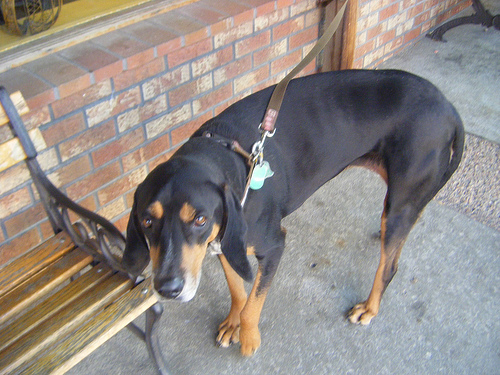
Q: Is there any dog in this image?
A: Yes, there is a dog.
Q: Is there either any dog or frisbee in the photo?
A: Yes, there is a dog.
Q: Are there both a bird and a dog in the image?
A: No, there is a dog but no birds.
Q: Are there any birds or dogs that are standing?
A: Yes, the dog is standing.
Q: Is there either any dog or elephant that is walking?
A: Yes, the dog is walking.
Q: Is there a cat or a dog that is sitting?
A: Yes, the dog is sitting.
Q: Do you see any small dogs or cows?
A: Yes, there is a small dog.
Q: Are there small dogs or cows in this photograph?
A: Yes, there is a small dog.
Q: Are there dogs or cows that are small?
A: Yes, the dog is small.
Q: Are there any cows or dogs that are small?
A: Yes, the dog is small.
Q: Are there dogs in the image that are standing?
A: Yes, there is a dog that is standing.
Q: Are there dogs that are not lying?
A: Yes, there is a dog that is standing.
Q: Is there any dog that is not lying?
A: Yes, there is a dog that is standing.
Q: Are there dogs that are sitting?
A: Yes, there is a dog that is sitting.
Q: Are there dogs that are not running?
A: Yes, there is a dog that is sitting.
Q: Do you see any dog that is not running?
A: Yes, there is a dog that is sitting .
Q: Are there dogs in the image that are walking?
A: Yes, there is a dog that is walking.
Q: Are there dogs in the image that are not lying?
A: Yes, there is a dog that is walking.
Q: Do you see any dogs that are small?
A: Yes, there is a small dog.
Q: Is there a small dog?
A: Yes, there is a small dog.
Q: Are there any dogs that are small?
A: Yes, there is a dog that is small.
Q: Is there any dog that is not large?
A: Yes, there is a small dog.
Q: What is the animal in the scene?
A: The animal is a dog.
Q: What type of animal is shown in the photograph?
A: The animal is a dog.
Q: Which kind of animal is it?
A: The animal is a dog.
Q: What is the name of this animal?
A: That is a dog.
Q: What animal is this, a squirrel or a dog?
A: That is a dog.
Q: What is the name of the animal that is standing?
A: The animal is a dog.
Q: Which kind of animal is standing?
A: The animal is a dog.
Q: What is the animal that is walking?
A: The animal is a dog.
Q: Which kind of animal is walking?
A: The animal is a dog.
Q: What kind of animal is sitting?
A: The animal is a dog.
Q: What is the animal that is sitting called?
A: The animal is a dog.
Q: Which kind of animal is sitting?
A: The animal is a dog.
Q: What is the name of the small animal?
A: The animal is a dog.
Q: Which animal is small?
A: The animal is a dog.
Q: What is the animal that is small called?
A: The animal is a dog.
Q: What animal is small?
A: The animal is a dog.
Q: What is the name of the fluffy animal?
A: The animal is a dog.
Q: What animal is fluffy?
A: The animal is a dog.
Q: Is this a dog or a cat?
A: This is a dog.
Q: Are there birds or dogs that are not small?
A: No, there is a dog but it is small.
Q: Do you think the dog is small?
A: Yes, the dog is small.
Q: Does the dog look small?
A: Yes, the dog is small.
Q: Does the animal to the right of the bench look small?
A: Yes, the dog is small.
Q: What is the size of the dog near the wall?
A: The dog is small.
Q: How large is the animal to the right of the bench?
A: The dog is small.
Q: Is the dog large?
A: No, the dog is small.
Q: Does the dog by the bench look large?
A: No, the dog is small.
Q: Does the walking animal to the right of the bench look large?
A: No, the dog is small.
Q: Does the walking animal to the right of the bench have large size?
A: No, the dog is small.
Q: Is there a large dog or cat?
A: No, there is a dog but it is small.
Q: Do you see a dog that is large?
A: No, there is a dog but it is small.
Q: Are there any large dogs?
A: No, there is a dog but it is small.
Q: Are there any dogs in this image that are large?
A: No, there is a dog but it is small.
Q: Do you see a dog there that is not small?
A: No, there is a dog but it is small.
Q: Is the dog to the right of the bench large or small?
A: The dog is small.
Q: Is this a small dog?
A: Yes, this is a small dog.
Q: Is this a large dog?
A: No, this is a small dog.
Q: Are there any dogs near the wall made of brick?
A: Yes, there is a dog near the wall.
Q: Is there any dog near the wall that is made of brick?
A: Yes, there is a dog near the wall.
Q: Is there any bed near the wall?
A: No, there is a dog near the wall.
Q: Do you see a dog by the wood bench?
A: Yes, there is a dog by the bench.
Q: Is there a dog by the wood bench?
A: Yes, there is a dog by the bench.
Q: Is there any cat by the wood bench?
A: No, there is a dog by the bench.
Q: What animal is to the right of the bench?
A: The animal is a dog.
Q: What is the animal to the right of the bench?
A: The animal is a dog.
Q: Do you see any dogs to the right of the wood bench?
A: Yes, there is a dog to the right of the bench.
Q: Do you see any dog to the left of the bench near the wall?
A: No, the dog is to the right of the bench.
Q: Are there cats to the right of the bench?
A: No, there is a dog to the right of the bench.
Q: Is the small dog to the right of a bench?
A: Yes, the dog is to the right of a bench.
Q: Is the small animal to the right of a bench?
A: Yes, the dog is to the right of a bench.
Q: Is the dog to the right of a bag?
A: No, the dog is to the right of a bench.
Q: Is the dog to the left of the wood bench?
A: No, the dog is to the right of the bench.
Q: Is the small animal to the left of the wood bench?
A: No, the dog is to the right of the bench.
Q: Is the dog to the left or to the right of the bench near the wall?
A: The dog is to the right of the bench.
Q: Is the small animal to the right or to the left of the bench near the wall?
A: The dog is to the right of the bench.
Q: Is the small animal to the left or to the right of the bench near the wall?
A: The dog is to the right of the bench.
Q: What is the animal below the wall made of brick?
A: The animal is a dog.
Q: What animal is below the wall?
A: The animal is a dog.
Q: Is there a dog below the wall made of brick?
A: Yes, there is a dog below the wall.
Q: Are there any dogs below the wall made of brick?
A: Yes, there is a dog below the wall.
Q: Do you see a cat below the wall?
A: No, there is a dog below the wall.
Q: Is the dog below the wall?
A: Yes, the dog is below the wall.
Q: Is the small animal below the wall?
A: Yes, the dog is below the wall.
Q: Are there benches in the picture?
A: Yes, there is a bench.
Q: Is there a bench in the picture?
A: Yes, there is a bench.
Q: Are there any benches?
A: Yes, there is a bench.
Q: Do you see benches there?
A: Yes, there is a bench.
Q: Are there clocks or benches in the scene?
A: Yes, there is a bench.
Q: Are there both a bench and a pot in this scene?
A: No, there is a bench but no pots.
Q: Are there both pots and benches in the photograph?
A: No, there is a bench but no pots.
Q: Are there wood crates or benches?
A: Yes, there is a wood bench.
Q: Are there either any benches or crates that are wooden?
A: Yes, the bench is wooden.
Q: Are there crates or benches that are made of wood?
A: Yes, the bench is made of wood.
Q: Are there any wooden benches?
A: Yes, there is a wood bench.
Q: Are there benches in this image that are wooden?
A: Yes, there is a bench that is wooden.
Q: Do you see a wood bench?
A: Yes, there is a bench that is made of wood.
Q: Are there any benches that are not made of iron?
A: Yes, there is a bench that is made of wood.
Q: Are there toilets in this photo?
A: No, there are no toilets.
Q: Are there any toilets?
A: No, there are no toilets.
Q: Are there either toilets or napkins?
A: No, there are no toilets or napkins.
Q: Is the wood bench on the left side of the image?
A: Yes, the bench is on the left of the image.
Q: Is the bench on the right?
A: No, the bench is on the left of the image.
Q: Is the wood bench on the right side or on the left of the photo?
A: The bench is on the left of the image.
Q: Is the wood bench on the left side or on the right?
A: The bench is on the left of the image.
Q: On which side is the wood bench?
A: The bench is on the left of the image.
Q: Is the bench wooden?
A: Yes, the bench is wooden.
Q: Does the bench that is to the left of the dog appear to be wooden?
A: Yes, the bench is wooden.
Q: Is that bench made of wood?
A: Yes, the bench is made of wood.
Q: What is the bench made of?
A: The bench is made of wood.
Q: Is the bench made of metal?
A: No, the bench is made of wood.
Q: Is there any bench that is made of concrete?
A: No, there is a bench but it is made of wood.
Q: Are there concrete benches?
A: No, there is a bench but it is made of wood.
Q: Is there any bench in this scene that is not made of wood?
A: No, there is a bench but it is made of wood.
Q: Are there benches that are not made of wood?
A: No, there is a bench but it is made of wood.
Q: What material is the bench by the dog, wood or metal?
A: The bench is made of wood.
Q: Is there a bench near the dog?
A: Yes, there is a bench near the dog.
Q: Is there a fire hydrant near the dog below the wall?
A: No, there is a bench near the dog.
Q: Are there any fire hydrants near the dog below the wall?
A: No, there is a bench near the dog.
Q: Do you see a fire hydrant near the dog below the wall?
A: No, there is a bench near the dog.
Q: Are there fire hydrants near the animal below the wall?
A: No, there is a bench near the dog.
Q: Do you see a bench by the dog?
A: Yes, there is a bench by the dog.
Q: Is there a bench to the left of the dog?
A: Yes, there is a bench to the left of the dog.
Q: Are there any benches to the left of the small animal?
A: Yes, there is a bench to the left of the dog.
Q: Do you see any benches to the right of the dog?
A: No, the bench is to the left of the dog.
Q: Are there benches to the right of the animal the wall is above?
A: No, the bench is to the left of the dog.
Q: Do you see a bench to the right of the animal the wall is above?
A: No, the bench is to the left of the dog.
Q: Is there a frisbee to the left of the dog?
A: No, there is a bench to the left of the dog.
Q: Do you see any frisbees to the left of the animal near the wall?
A: No, there is a bench to the left of the dog.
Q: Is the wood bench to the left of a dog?
A: Yes, the bench is to the left of a dog.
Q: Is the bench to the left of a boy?
A: No, the bench is to the left of a dog.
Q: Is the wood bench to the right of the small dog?
A: No, the bench is to the left of the dog.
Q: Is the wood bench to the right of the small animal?
A: No, the bench is to the left of the dog.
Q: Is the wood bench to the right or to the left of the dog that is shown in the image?
A: The bench is to the left of the dog.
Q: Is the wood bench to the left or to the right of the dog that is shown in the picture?
A: The bench is to the left of the dog.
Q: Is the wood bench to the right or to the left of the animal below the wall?
A: The bench is to the left of the dog.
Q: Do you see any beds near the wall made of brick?
A: No, there is a bench near the wall.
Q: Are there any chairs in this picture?
A: No, there are no chairs.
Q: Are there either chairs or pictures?
A: No, there are no chairs or pictures.